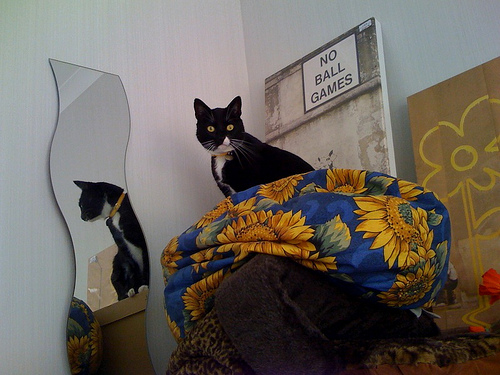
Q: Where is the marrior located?
A: On the left wall.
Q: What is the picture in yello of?
A: A flower.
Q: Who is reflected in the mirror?
A: A cat.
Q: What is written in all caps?
A: NO BALL GAMES.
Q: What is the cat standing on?
A: A flower blankent.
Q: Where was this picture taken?
A: A bed room.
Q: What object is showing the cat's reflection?
A: Mirror on the wall.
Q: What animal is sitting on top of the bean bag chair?
A: A cat.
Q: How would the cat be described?
A: It is black with a little white in it.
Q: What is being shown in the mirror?
A: The cat's reflection.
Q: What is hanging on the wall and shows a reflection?
A: A mirror.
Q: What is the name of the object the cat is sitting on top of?
A: A duvee.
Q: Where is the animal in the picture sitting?
A: The tuxedo cat is sitting on top of a shelf.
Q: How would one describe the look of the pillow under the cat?
A: Blue and gold pillow with flowers on it.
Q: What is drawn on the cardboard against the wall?
A: A flower.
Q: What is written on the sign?
A: NO BALL GAMES.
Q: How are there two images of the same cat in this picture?
A: The reflection in the mirror.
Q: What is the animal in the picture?
A: A cat.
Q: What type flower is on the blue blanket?
A: A sunflower.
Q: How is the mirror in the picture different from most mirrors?
A: It is curvy.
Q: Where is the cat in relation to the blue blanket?
A: Behind it.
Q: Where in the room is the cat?
A: The corner.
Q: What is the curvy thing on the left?
A: A mirror.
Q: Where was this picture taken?
A: Inside a house.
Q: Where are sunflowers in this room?
A: On the blue fabric.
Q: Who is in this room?
A: A cat.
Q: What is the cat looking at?
A: The camera.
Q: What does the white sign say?
A: No ball games.